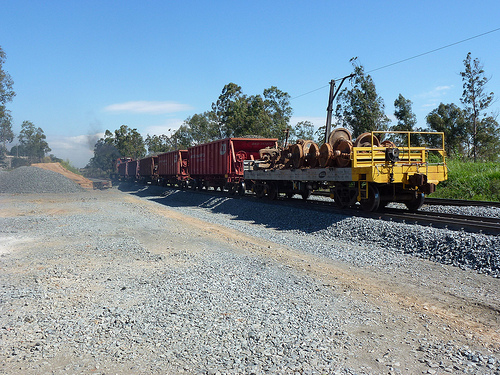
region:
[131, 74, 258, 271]
a train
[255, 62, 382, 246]
a train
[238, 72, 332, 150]
a train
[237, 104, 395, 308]
a train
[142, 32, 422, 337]
a train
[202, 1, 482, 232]
a train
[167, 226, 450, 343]
tire tracks in gravel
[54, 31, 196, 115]
cloud in the blue sky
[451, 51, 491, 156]
tree outside and clear sky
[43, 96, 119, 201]
grey smoke and pile of brown dirt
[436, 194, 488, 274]
train tracks on top of gravel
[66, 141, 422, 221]
carts being pulled on tracks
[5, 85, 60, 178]
green tree next to pile of dirt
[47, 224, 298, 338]
gravel outside with dirt underneath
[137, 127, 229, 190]
three red carts on train tracks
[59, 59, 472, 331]
train driving along tracks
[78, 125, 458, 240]
a small goods truck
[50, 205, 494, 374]
small stones in track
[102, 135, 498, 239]
a long rail way track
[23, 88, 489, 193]
beautiful view of trees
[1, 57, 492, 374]
group of trees aside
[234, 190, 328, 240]
shadow of the train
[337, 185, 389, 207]
wheel of the train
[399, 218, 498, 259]
hard rock stones in track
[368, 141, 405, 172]
a black object in back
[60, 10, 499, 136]
beautiful view of sky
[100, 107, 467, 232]
train on the tracks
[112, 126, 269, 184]
four red train cars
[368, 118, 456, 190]
yellow railing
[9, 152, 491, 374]
gravel along the side of the train tracks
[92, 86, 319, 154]
tree tops visible over the train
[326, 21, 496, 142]
powerline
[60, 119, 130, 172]
smoke coming off the train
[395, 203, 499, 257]
train tracks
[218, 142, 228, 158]
logo on the train car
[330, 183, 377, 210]
two black wheels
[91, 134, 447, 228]
a small rail on track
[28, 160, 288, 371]
a uniform stones in road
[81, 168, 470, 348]
a white root beside track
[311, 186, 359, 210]
wheel of the train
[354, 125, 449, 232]
back part of the train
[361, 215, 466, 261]
a group of large stones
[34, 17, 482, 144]
a beautiful view of sky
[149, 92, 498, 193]
a large group of trees